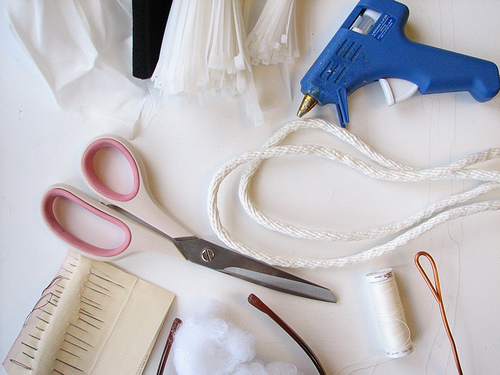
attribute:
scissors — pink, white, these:
[40, 130, 341, 303]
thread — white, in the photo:
[361, 263, 417, 367]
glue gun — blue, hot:
[296, 2, 500, 127]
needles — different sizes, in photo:
[4, 252, 182, 373]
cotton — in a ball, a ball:
[167, 315, 306, 374]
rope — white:
[198, 107, 500, 276]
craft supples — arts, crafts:
[68, 9, 464, 345]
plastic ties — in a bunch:
[159, 2, 307, 110]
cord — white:
[392, 145, 500, 238]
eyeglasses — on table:
[245, 291, 333, 372]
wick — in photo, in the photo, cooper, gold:
[412, 248, 462, 373]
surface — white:
[148, 110, 214, 191]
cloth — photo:
[1, 1, 158, 127]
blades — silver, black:
[126, 0, 169, 78]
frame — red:
[152, 319, 187, 373]